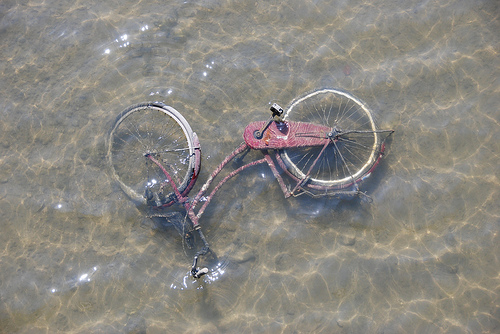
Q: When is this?
A: Daytime.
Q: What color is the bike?
A: Red.